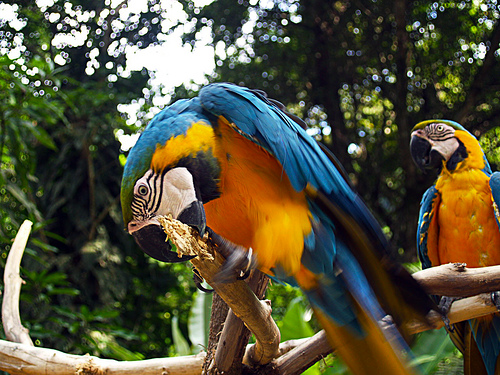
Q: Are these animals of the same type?
A: Yes, all the animals are parrots.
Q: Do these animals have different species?
A: No, all the animals are parrots.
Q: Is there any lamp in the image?
A: No, there are no lamps.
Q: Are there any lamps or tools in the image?
A: No, there are no lamps or tools.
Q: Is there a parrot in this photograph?
A: Yes, there is a parrot.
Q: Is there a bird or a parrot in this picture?
A: Yes, there is a parrot.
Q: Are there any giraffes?
A: No, there are no giraffes.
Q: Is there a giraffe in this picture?
A: No, there are no giraffes.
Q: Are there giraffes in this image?
A: No, there are no giraffes.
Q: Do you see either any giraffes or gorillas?
A: No, there are no giraffes or gorillas.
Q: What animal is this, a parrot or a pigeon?
A: This is a parrot.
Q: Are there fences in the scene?
A: No, there are no fences.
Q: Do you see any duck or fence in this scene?
A: No, there are no fences or ducks.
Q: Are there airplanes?
A: No, there are no airplanes.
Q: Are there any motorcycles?
A: No, there are no motorcycles.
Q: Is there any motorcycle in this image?
A: No, there are no motorcycles.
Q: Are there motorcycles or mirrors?
A: No, there are no motorcycles or mirrors.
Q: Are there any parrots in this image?
A: Yes, there is a parrot.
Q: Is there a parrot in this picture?
A: Yes, there is a parrot.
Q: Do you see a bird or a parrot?
A: Yes, there is a parrot.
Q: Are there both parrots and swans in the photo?
A: No, there is a parrot but no swans.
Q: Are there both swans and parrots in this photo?
A: No, there is a parrot but no swans.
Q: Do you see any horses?
A: No, there are no horses.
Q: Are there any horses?
A: No, there are no horses.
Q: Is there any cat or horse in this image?
A: No, there are no horses or cats.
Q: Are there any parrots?
A: Yes, there are parrots.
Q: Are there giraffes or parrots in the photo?
A: Yes, there are parrots.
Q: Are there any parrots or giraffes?
A: Yes, there are parrots.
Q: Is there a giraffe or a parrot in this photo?
A: Yes, there are parrots.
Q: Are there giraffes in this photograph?
A: No, there are no giraffes.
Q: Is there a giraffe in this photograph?
A: No, there are no giraffes.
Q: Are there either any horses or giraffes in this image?
A: No, there are no giraffes or horses.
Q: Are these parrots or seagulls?
A: These are parrots.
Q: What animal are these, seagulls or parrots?
A: These are parrots.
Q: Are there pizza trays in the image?
A: No, there are no pizza trays.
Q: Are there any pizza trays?
A: No, there are no pizza trays.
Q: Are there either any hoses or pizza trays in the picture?
A: No, there are no pizza trays or hoses.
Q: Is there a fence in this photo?
A: No, there are no fences.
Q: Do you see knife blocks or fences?
A: No, there are no fences or knife blocks.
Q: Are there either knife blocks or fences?
A: No, there are no fences or knife blocks.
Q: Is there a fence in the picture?
A: No, there are no fences.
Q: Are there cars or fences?
A: No, there are no fences or cars.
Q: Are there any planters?
A: No, there are no planters.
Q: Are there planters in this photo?
A: No, there are no planters.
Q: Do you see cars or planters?
A: No, there are no planters or cars.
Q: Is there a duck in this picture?
A: No, there are no ducks.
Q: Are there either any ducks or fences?
A: No, there are no ducks or fences.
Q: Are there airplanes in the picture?
A: No, there are no airplanes.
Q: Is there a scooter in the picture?
A: No, there are no scooters.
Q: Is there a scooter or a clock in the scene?
A: No, there are no scooters or clocks.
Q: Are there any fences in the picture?
A: No, there are no fences.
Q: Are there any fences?
A: No, there are no fences.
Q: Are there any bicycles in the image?
A: No, there are no bicycles.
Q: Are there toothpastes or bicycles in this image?
A: No, there are no bicycles or toothpastes.